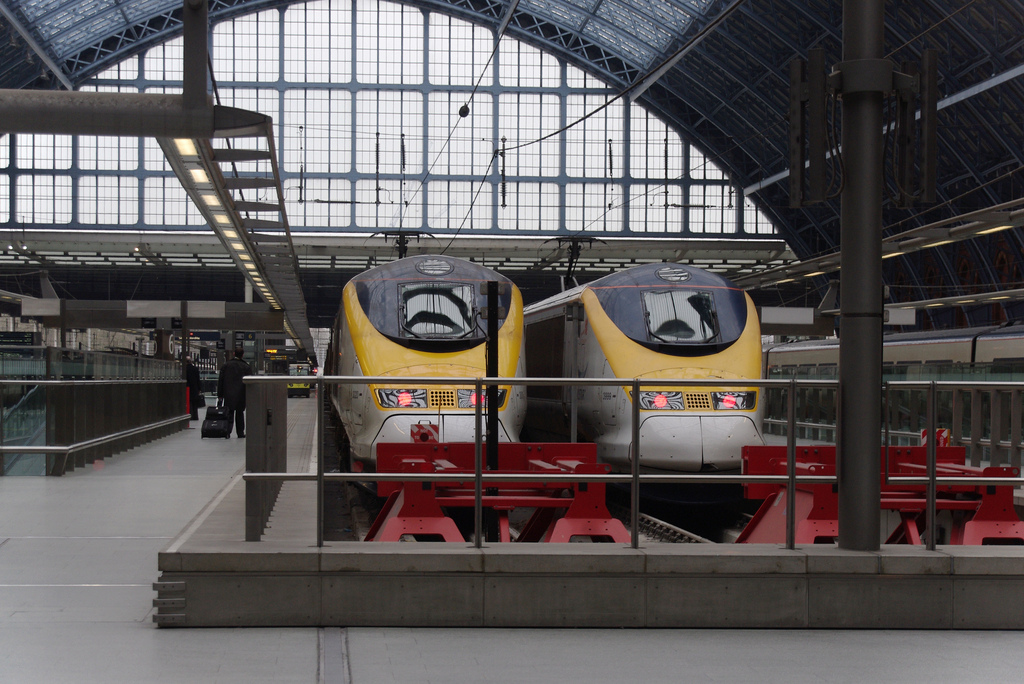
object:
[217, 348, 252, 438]
man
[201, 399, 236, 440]
suitcase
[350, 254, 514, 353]
windshield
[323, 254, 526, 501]
train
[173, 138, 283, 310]
lights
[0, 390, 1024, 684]
platform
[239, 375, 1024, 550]
rail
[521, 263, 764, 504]
train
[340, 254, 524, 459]
front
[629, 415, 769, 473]
bottom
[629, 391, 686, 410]
light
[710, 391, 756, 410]
light